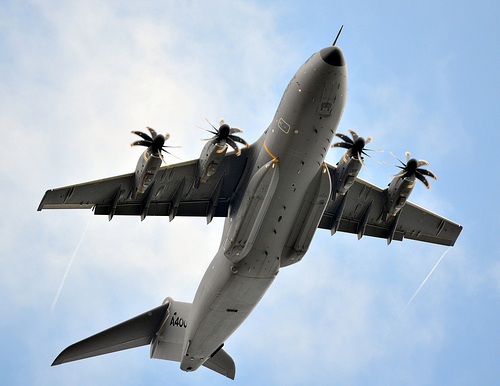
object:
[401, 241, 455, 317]
jetstream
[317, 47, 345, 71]
nose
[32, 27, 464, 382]
airplane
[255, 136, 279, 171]
strip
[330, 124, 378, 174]
propeller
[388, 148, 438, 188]
propeller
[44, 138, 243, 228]
wing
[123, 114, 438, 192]
propellers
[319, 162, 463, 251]
wing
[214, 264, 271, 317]
landing wheel cover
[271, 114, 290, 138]
door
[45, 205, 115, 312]
jetstream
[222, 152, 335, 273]
stabilizers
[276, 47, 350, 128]
cockpit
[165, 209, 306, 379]
fuselage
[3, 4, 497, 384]
sky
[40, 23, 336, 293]
clouds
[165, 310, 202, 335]
letters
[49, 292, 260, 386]
tail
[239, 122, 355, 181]
highlights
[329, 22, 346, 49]
antenna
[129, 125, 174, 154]
blades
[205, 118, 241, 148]
blades